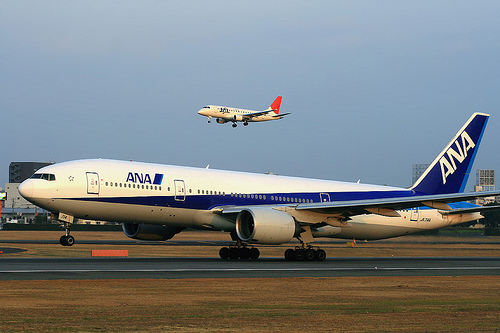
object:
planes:
[18, 113, 500, 260]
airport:
[0, 0, 499, 329]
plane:
[198, 94, 290, 128]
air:
[131, 35, 191, 92]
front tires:
[60, 235, 76, 247]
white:
[207, 172, 251, 185]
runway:
[0, 258, 500, 279]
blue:
[427, 174, 435, 190]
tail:
[269, 96, 288, 119]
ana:
[441, 130, 477, 186]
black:
[219, 247, 227, 256]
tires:
[283, 249, 295, 260]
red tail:
[268, 95, 283, 119]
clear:
[86, 21, 299, 81]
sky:
[0, 0, 500, 198]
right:
[85, 149, 474, 270]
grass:
[0, 274, 500, 333]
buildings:
[23, 206, 180, 236]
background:
[0, 0, 500, 333]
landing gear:
[288, 206, 350, 227]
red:
[274, 101, 279, 109]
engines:
[231, 210, 305, 244]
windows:
[110, 181, 112, 188]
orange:
[91, 250, 124, 257]